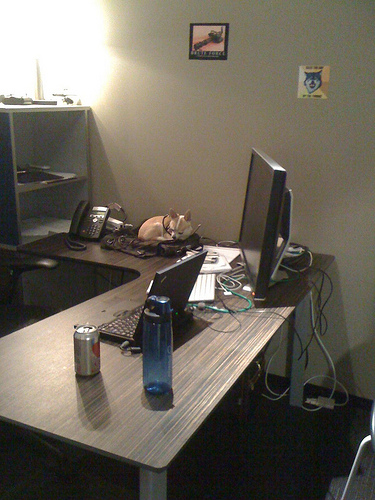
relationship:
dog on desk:
[136, 206, 193, 246] [1, 216, 336, 399]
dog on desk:
[138, 208, 193, 243] [0, 195, 349, 493]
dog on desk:
[138, 208, 193, 243] [3, 228, 335, 472]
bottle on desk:
[140, 294, 172, 394] [0, 195, 349, 493]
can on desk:
[72, 323, 101, 377] [0, 195, 349, 493]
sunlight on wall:
[3, 4, 103, 94] [0, 1, 372, 408]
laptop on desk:
[76, 240, 213, 357] [0, 195, 349, 493]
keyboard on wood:
[191, 274, 219, 305] [3, 218, 331, 469]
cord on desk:
[252, 236, 344, 427] [0, 195, 349, 493]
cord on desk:
[208, 247, 249, 314] [0, 195, 349, 493]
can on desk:
[73, 324, 100, 377] [18, 228, 329, 488]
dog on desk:
[138, 208, 193, 243] [22, 213, 360, 468]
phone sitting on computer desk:
[56, 197, 111, 253] [0, 229, 335, 497]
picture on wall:
[297, 64, 328, 99] [10, 0, 363, 276]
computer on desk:
[234, 148, 295, 303] [0, 224, 337, 498]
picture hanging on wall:
[189, 22, 228, 61] [109, 57, 223, 152]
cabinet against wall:
[1, 96, 100, 301] [127, 101, 208, 170]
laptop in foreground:
[98, 249, 208, 349] [28, 257, 315, 402]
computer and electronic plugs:
[234, 143, 295, 303] [261, 238, 351, 408]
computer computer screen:
[234, 148, 295, 303] [215, 141, 299, 295]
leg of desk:
[137, 467, 170, 498] [0, 224, 337, 498]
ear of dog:
[168, 207, 176, 219] [138, 208, 193, 243]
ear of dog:
[184, 205, 192, 223] [138, 208, 193, 243]